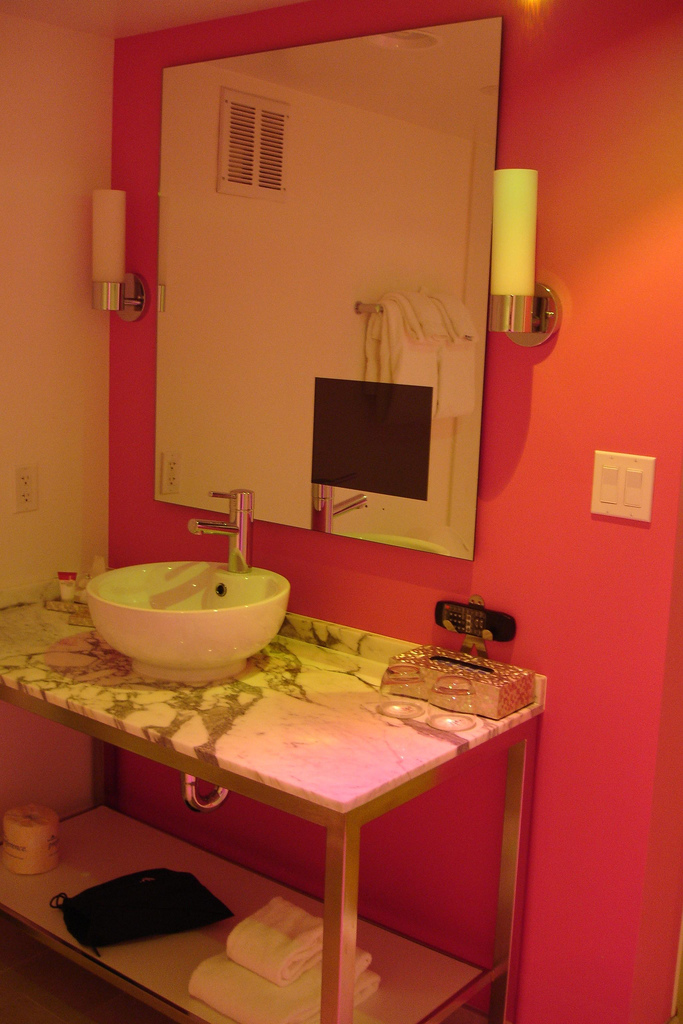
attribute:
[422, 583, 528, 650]
remote control — black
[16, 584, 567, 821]
countertop — marble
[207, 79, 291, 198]
air vent — white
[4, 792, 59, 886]
toilet paper — white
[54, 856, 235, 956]
bag — black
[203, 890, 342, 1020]
towel — small, white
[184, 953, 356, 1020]
towel — white, large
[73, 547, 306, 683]
sink — white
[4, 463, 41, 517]
outlet — small, white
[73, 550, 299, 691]
sink — white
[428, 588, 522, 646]
remote control — black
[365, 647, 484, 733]
glasses — clear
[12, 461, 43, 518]
outlet — ELECTRICAL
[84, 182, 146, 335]
lamp — WALL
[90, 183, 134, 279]
globe — WHITE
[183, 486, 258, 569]
faucet — SILVER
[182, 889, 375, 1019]
towels — FOLDED, WHITE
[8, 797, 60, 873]
roll — WRAPPED UP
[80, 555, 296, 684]
bowl —  SMALL,  WHITE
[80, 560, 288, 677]
sink — WHITE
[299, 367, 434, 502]
mirror — SMALL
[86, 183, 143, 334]
fixture — SMALL, LIGHT